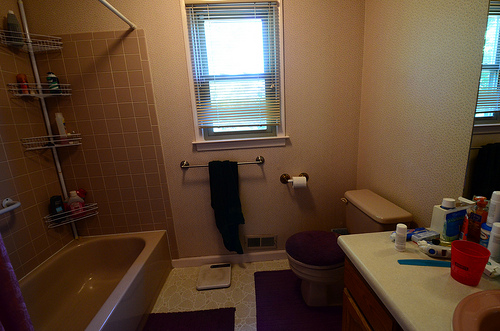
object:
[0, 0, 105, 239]
organizer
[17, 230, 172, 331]
bathtub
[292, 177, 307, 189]
napkin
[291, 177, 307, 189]
napkin roll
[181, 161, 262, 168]
bar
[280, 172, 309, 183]
holder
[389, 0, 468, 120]
wall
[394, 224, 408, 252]
bottle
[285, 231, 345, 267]
toilet cover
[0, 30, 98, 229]
rack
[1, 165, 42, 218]
wall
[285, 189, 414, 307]
toilet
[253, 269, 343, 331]
rug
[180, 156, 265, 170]
hanger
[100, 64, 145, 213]
wall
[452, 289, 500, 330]
sink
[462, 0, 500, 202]
mirror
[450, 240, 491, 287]
cup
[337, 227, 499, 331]
counter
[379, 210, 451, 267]
thermometer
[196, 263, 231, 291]
scale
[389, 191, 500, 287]
toiletries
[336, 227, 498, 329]
vanity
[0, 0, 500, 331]
bathroom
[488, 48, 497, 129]
reflection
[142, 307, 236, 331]
mat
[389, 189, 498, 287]
items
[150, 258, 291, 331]
floor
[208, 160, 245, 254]
towel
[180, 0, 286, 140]
blinds